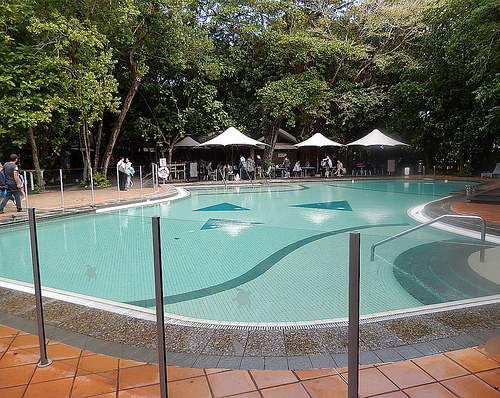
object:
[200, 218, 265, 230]
triangles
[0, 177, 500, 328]
pool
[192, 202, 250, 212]
triangles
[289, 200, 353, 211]
triangles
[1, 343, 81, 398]
tiles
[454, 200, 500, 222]
tiles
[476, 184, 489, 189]
tiles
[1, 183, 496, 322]
water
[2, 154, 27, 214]
man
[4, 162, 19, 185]
shirt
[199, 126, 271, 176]
umbrella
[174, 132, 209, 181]
umbrella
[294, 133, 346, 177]
umbrella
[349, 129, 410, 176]
umbrella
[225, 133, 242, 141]
white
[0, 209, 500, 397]
fence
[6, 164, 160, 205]
fence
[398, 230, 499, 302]
steps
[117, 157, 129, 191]
man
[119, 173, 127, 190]
pants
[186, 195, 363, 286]
swimming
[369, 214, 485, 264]
handrail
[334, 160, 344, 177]
people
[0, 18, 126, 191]
trees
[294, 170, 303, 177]
chairs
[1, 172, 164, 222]
sidewalk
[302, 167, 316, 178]
tables and chairs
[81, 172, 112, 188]
plants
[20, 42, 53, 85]
green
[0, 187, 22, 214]
jeans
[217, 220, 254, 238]
reflections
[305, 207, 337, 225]
reflections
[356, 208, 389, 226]
reflections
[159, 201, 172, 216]
reflections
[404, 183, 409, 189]
reflections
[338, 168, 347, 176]
chairs